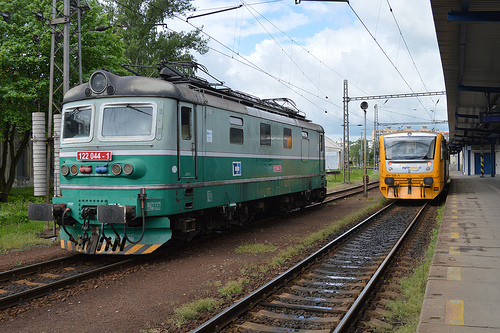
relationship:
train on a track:
[379, 126, 451, 204] [184, 155, 453, 333]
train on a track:
[56, 70, 328, 254] [4, 173, 378, 297]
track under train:
[184, 155, 453, 333] [379, 126, 451, 204]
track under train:
[4, 173, 378, 297] [56, 70, 328, 254]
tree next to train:
[1, 1, 66, 206] [56, 70, 328, 254]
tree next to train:
[50, 0, 120, 113] [56, 70, 328, 254]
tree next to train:
[106, 0, 207, 81] [56, 70, 328, 254]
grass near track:
[2, 212, 62, 257] [4, 173, 378, 297]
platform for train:
[410, 171, 500, 327] [379, 126, 451, 204]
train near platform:
[379, 126, 451, 204] [410, 171, 500, 327]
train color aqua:
[379, 126, 451, 204] [67, 97, 326, 211]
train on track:
[56, 70, 328, 254] [4, 173, 378, 297]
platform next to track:
[410, 171, 500, 327] [184, 155, 453, 333]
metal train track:
[187, 198, 446, 327] [184, 155, 453, 333]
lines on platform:
[447, 178, 468, 333] [410, 171, 500, 327]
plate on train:
[77, 151, 113, 165] [56, 70, 328, 254]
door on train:
[177, 100, 198, 184] [56, 70, 328, 254]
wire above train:
[337, 1, 443, 136] [379, 126, 451, 204]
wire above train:
[378, 0, 463, 130] [379, 126, 451, 204]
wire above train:
[70, 1, 376, 132] [56, 70, 328, 254]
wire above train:
[207, 0, 377, 127] [56, 70, 328, 254]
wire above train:
[237, 0, 436, 124] [56, 70, 328, 254]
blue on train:
[67, 97, 326, 211] [56, 70, 328, 254]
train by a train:
[379, 126, 451, 204] [56, 70, 328, 254]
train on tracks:
[56, 70, 328, 254] [4, 173, 378, 297]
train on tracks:
[379, 126, 451, 204] [184, 155, 453, 333]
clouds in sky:
[23, 0, 448, 137] [77, 1, 448, 133]